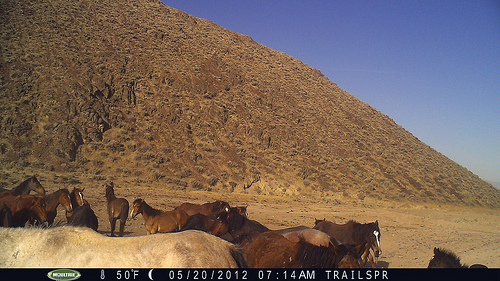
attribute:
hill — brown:
[13, 11, 479, 196]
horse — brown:
[316, 219, 383, 256]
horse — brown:
[235, 228, 343, 273]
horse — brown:
[127, 198, 187, 232]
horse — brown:
[100, 180, 127, 234]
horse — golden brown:
[127, 196, 194, 238]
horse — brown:
[93, 178, 127, 229]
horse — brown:
[314, 212, 386, 262]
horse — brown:
[59, 173, 104, 232]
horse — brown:
[229, 223, 297, 270]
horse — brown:
[228, 229, 362, 271]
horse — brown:
[310, 219, 382, 269]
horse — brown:
[127, 195, 192, 232]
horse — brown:
[0, 192, 47, 222]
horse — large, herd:
[102, 179, 128, 235]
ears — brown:
[362, 216, 382, 226]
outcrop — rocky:
[43, 73, 155, 168]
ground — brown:
[1, 185, 497, 267]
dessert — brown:
[384, 196, 494, 251]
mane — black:
[289, 244, 347, 268]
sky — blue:
[381, 42, 467, 86]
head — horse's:
[365, 215, 390, 264]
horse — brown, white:
[316, 222, 383, 259]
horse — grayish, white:
[7, 206, 259, 266]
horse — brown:
[3, 185, 63, 229]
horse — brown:
[177, 198, 231, 215]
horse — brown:
[182, 205, 247, 232]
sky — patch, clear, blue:
[345, 15, 482, 99]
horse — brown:
[184, 214, 262, 235]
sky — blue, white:
[207, 5, 490, 141]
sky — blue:
[182, 1, 498, 193]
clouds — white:
[354, 36, 498, 182]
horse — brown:
[129, 192, 189, 242]